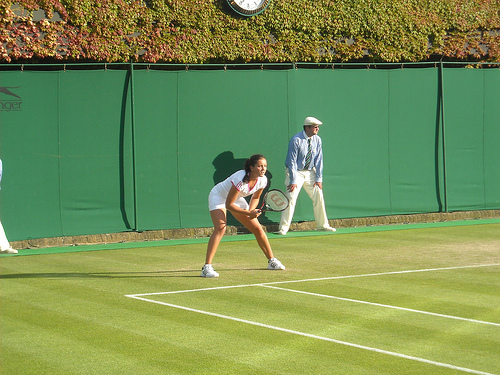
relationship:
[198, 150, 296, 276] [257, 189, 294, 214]
woman with racquet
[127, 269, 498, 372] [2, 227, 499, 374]
lines on tennis court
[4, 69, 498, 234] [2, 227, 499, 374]
canvas around tennis court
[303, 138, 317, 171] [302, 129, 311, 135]
tie on neck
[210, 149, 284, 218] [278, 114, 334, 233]
shadow of man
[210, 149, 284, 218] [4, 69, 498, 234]
shadow on canvas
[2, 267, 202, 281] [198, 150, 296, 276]
shadow of woman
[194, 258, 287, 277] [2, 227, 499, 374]
shoes on tennis court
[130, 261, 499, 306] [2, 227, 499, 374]
line on tennis court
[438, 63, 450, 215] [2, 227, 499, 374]
pole on tennis court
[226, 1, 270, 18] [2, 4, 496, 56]
clock on ivy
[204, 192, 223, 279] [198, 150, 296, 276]
leg of woman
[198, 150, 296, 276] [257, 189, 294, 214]
woman holding racquet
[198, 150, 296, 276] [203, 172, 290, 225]
woman in gear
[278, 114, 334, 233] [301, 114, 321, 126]
man with hat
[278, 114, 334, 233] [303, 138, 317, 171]
man wearing tie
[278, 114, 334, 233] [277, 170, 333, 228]
man wearing pants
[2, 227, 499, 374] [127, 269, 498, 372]
tennis court with lines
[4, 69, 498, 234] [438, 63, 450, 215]
canvas with pole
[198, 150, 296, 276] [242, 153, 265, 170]
woman has hair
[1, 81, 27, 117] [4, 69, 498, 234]
logo on canvas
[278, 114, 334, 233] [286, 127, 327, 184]
man in shirt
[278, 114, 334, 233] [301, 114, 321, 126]
man in hat